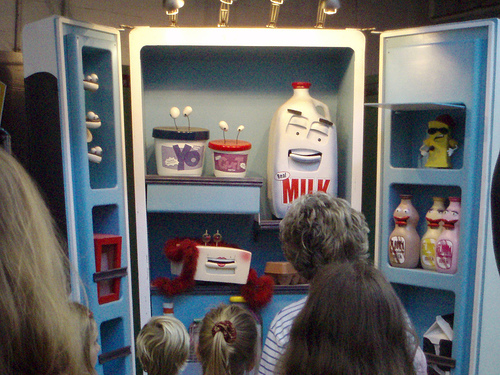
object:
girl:
[193, 301, 261, 375]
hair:
[196, 301, 268, 375]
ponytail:
[201, 331, 235, 374]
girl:
[273, 192, 420, 374]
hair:
[274, 189, 416, 375]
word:
[171, 142, 202, 175]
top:
[290, 80, 314, 90]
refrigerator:
[19, 17, 500, 374]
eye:
[285, 115, 312, 142]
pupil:
[294, 130, 301, 136]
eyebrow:
[287, 109, 305, 116]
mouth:
[288, 148, 322, 164]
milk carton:
[263, 79, 340, 221]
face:
[278, 105, 337, 178]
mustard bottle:
[416, 113, 459, 171]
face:
[426, 125, 450, 147]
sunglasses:
[428, 125, 451, 137]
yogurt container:
[152, 126, 210, 179]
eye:
[182, 106, 192, 118]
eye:
[167, 105, 181, 119]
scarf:
[150, 235, 277, 312]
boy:
[129, 315, 196, 374]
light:
[313, 0, 340, 31]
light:
[265, 0, 288, 27]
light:
[217, 0, 237, 29]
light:
[158, 0, 188, 27]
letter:
[282, 176, 300, 207]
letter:
[300, 176, 309, 202]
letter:
[308, 179, 314, 199]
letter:
[315, 178, 333, 197]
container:
[207, 139, 254, 179]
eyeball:
[223, 126, 227, 130]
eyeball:
[237, 128, 243, 132]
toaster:
[170, 241, 253, 289]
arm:
[156, 237, 202, 297]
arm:
[244, 268, 276, 308]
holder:
[211, 319, 237, 339]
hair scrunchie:
[204, 332, 238, 375]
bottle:
[386, 190, 422, 271]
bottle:
[434, 191, 461, 274]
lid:
[151, 126, 213, 144]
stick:
[186, 115, 193, 134]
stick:
[173, 117, 182, 133]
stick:
[222, 129, 228, 146]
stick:
[235, 130, 242, 146]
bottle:
[420, 190, 449, 274]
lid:
[430, 192, 447, 204]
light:
[398, 27, 459, 82]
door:
[373, 17, 500, 374]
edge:
[124, 23, 368, 339]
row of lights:
[158, 0, 342, 30]